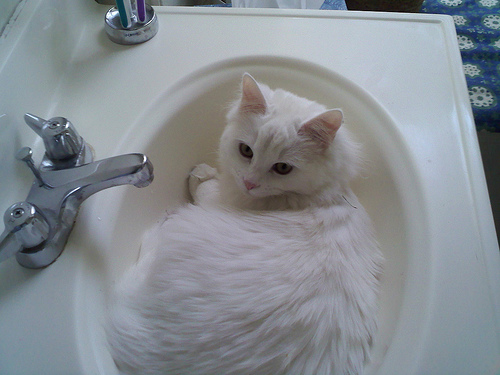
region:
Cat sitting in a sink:
[101, 83, 420, 373]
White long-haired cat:
[118, 73, 415, 374]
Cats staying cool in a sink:
[107, 69, 381, 374]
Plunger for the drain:
[13, 143, 46, 188]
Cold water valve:
[19, 96, 85, 165]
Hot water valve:
[0, 193, 46, 270]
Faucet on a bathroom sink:
[0, 96, 163, 282]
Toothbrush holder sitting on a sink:
[92, 3, 169, 42]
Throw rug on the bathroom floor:
[421, 4, 498, 106]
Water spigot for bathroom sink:
[84, 146, 155, 195]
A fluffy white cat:
[119, 72, 386, 372]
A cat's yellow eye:
[273, 150, 293, 182]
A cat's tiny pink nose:
[240, 177, 262, 193]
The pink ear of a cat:
[301, 101, 343, 155]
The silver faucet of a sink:
[1, 115, 151, 273]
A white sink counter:
[318, 11, 461, 96]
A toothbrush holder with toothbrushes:
[103, 0, 165, 44]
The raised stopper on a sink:
[16, 144, 52, 184]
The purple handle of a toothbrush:
[134, 0, 150, 24]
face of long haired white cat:
[216, 77, 371, 197]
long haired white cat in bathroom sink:
[103, 72, 380, 372]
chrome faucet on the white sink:
[5, 114, 148, 270]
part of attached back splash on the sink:
[14, 2, 84, 117]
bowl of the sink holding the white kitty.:
[79, 55, 436, 373]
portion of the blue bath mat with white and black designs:
[453, 0, 499, 106]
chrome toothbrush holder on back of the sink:
[106, 4, 156, 44]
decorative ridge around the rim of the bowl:
[181, 52, 346, 82]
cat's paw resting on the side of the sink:
[185, 162, 228, 206]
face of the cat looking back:
[231, 134, 303, 199]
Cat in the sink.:
[180, 42, 431, 342]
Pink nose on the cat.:
[229, 168, 294, 219]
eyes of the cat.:
[231, 128, 322, 191]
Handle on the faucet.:
[17, 98, 112, 159]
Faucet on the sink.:
[7, 107, 192, 267]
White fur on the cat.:
[152, 187, 409, 352]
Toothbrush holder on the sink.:
[104, 10, 217, 64]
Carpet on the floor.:
[411, 4, 498, 61]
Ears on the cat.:
[225, 52, 402, 153]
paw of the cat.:
[170, 152, 233, 209]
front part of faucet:
[92, 155, 153, 185]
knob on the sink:
[24, 109, 79, 149]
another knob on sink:
[0, 205, 48, 241]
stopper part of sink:
[14, 140, 44, 192]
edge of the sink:
[437, 22, 482, 121]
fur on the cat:
[176, 235, 271, 287]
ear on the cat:
[297, 112, 355, 144]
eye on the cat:
[230, 137, 253, 162]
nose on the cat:
[240, 169, 258, 194]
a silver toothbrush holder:
[83, 2, 178, 39]